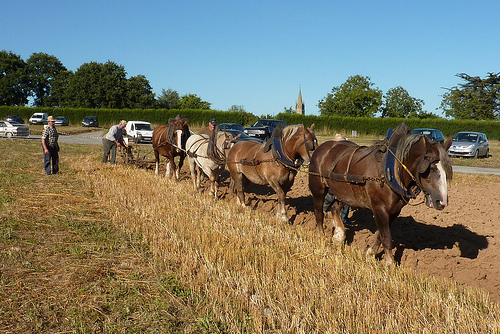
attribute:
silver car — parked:
[446, 125, 493, 160]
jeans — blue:
[40, 142, 60, 177]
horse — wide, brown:
[304, 121, 461, 268]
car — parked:
[27, 106, 47, 126]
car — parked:
[121, 118, 164, 157]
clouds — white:
[187, 40, 226, 93]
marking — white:
[434, 155, 452, 207]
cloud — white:
[194, 20, 351, 81]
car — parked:
[449, 129, 491, 159]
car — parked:
[409, 126, 444, 140]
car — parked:
[124, 118, 154, 141]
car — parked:
[81, 113, 99, 126]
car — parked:
[0, 118, 31, 138]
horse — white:
[180, 123, 236, 198]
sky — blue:
[259, 13, 353, 64]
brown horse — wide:
[152, 112, 188, 180]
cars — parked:
[415, 123, 490, 160]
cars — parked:
[29, 111, 99, 128]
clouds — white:
[252, 24, 394, 92]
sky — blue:
[208, 8, 333, 48]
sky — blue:
[162, 7, 332, 46]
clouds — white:
[406, 68, 443, 93]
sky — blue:
[134, 10, 403, 37]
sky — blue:
[211, 14, 400, 59]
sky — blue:
[158, 31, 224, 101]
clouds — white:
[309, 30, 375, 74]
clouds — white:
[371, 17, 429, 75]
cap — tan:
[43, 113, 58, 126]